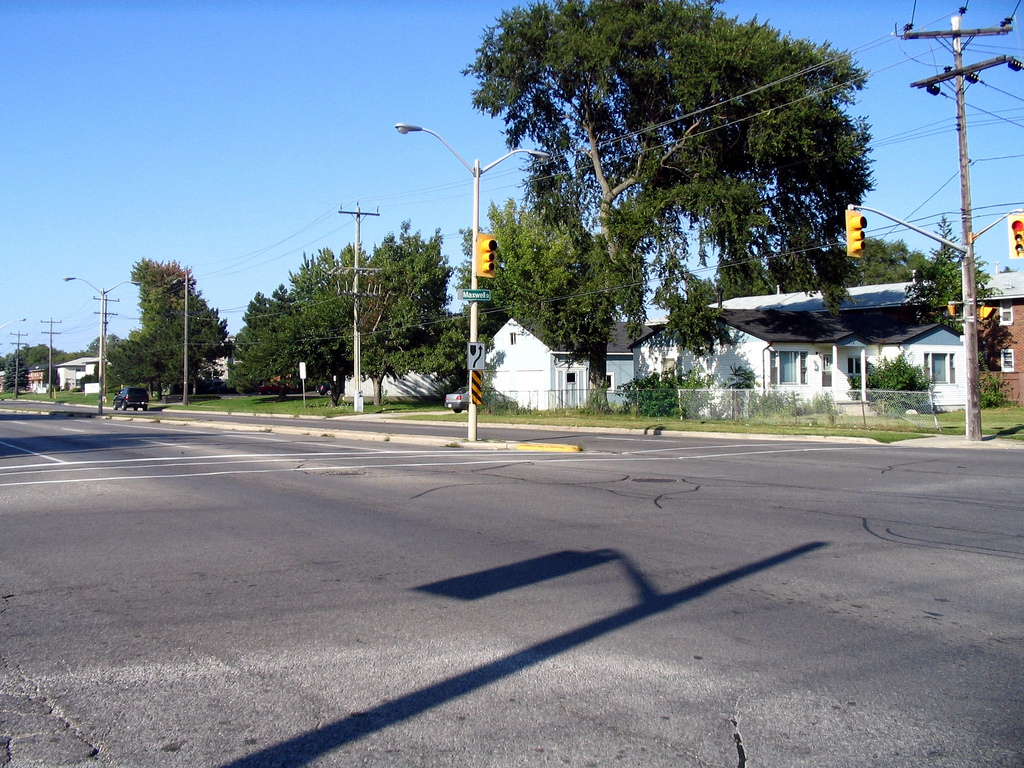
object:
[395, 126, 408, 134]
light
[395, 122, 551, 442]
street light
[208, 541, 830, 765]
shadows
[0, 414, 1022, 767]
ground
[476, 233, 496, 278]
traffic light casing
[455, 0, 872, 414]
tree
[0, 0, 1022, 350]
wires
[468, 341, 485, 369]
sign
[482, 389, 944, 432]
fence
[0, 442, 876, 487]
lines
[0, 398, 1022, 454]
curb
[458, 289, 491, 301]
street sign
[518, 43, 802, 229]
leaves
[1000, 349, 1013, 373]
window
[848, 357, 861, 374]
window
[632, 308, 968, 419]
house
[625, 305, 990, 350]
rooftop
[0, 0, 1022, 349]
sky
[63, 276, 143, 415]
poles